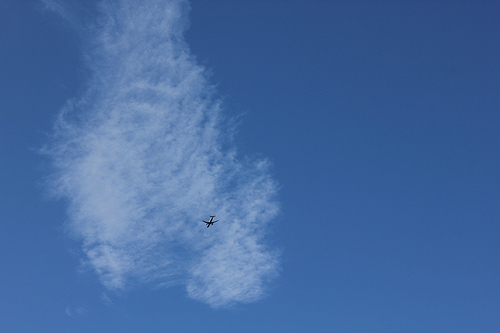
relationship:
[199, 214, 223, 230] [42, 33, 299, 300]
airplane flying through cloud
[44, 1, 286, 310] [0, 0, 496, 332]
clouds in sky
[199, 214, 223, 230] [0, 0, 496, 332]
airplane in sky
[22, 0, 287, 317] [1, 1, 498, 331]
clouds in blue sky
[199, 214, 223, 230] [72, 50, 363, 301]
airplane flying in sky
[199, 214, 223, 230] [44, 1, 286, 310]
airplane flying through clouds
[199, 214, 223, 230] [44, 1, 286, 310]
airplane flying next to clouds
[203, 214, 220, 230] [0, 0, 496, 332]
airplane flying through sky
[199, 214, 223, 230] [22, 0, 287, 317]
airplane flying through clouds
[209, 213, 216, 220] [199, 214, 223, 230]
tail end on airplane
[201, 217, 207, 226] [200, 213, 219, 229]
wing on airplane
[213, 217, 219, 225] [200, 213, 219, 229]
wing on airplane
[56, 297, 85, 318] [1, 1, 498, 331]
cloud in blue sky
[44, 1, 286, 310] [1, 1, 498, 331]
clouds in blue sky